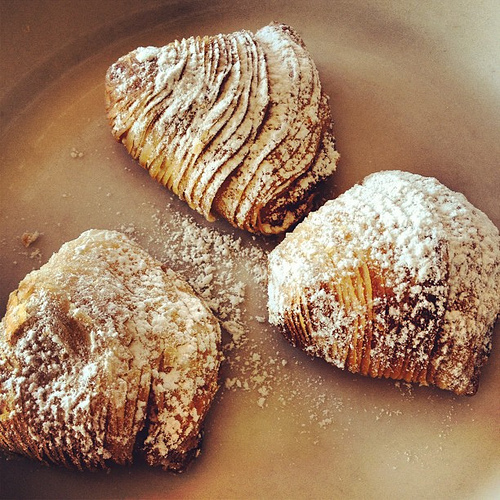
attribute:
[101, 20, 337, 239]
dessert — shaped, italian, brown, cone shaped, red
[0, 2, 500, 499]
plate — white, red, beige, smooth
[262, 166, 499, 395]
dessert — shaped, italian, brown, cone shaped, red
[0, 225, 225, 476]
dessert — shaped, italian, brown, cone shaped, red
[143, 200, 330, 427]
powdered sugar — scattered, white